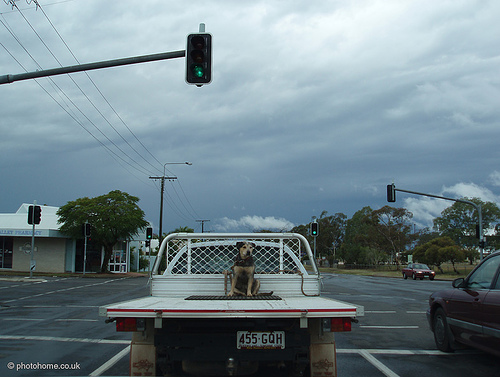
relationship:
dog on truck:
[226, 242, 273, 298] [97, 232, 366, 377]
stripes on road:
[338, 320, 443, 371] [347, 342, 437, 374]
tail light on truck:
[327, 319, 354, 333] [97, 232, 366, 377]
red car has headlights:
[402, 263, 436, 281] [412, 262, 441, 276]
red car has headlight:
[404, 261, 433, 281] [429, 268, 439, 277]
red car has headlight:
[404, 261, 433, 281] [413, 267, 424, 276]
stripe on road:
[351, 341, 436, 374] [343, 271, 399, 301]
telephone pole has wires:
[149, 171, 177, 248] [167, 180, 198, 232]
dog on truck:
[215, 221, 280, 293] [97, 232, 366, 377]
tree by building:
[69, 183, 148, 278] [2, 202, 148, 277]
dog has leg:
[226, 242, 273, 298] [229, 268, 238, 299]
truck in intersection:
[79, 203, 399, 352] [12, 266, 438, 318]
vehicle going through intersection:
[432, 249, 498, 366] [3, 166, 482, 375]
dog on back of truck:
[226, 242, 273, 298] [97, 232, 366, 377]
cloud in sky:
[207, 215, 292, 235] [5, 5, 495, 204]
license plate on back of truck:
[236, 322, 303, 354] [128, 232, 343, 371]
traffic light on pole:
[186, 33, 211, 84] [6, 50, 185, 86]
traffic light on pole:
[184, 28, 212, 84] [6, 50, 185, 86]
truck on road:
[97, 232, 366, 377] [5, 274, 498, 375]